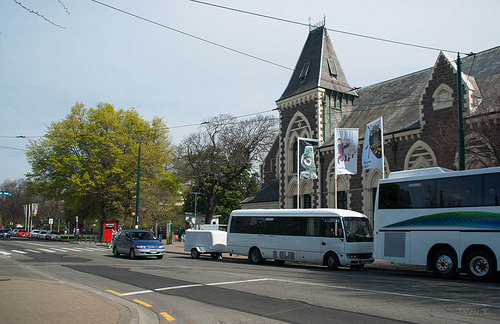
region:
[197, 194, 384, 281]
the bus is white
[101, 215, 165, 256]
the car is blue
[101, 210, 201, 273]
the car is blue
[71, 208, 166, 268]
the car is blue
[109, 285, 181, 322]
Small yellow dashes along the road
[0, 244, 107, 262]
A crosswalk in the street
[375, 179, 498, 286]
A large white bus on the road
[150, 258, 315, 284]
Grey pavement beneath the vehicles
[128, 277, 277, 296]
A dashed white line on the road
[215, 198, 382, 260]
A long white van behind the bus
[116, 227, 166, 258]
A small blue car driving on the road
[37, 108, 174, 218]
A healthy green tree in the distance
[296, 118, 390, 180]
Posters hanging from tall poles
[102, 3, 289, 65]
Telephone wires above the street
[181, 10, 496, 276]
bus, van and trailer in front of church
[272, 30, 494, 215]
white arches on dark facade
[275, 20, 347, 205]
tower with slanted roof part of church corner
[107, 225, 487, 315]
blue car being driving on street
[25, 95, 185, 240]
large round tree with greenish-yellow leaves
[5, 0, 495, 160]
wires crossing blue sky to church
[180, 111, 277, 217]
tree with bare branches in front of green tree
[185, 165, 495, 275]
black wheels on white vehicles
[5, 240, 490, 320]
white and yellow lines on street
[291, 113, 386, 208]
banners with illustrations in front of church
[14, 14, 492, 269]
picture taken outdoors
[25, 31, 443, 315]
picture taken during the day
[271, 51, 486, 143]
a large church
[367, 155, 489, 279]
a bus is parked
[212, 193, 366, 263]
a smaller bus is behind the big bus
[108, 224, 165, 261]
a blue car on the street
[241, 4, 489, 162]
telephone wires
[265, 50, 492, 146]
the building is ornate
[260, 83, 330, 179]
the building is made of brick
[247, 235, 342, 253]
the bus is white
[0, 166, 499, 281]
Several vehicle in a busy road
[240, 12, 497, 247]
A church like building on road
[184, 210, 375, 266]
The white van pulling a trailer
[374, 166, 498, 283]
The double rear wheeled bus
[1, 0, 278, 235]
The green tree in a clear sky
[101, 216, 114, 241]
The red booth in the background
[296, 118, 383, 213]
The flags opposite the building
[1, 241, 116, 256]
A zebra crossing in busy road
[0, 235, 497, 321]
The dark tarmacked road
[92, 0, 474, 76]
The wire cables attached to the building